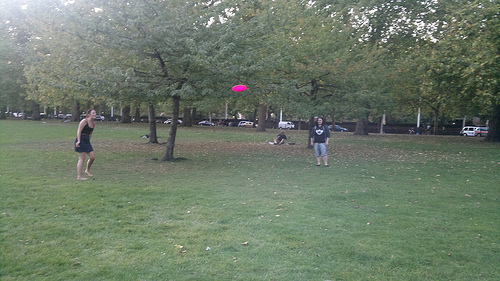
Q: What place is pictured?
A: It is a park.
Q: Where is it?
A: This is at the park.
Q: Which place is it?
A: It is a park.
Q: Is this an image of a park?
A: Yes, it is showing a park.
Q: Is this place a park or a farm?
A: It is a park.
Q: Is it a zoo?
A: No, it is a park.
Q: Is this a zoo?
A: No, it is a park.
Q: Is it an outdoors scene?
A: Yes, it is outdoors.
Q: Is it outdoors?
A: Yes, it is outdoors.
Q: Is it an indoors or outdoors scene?
A: It is outdoors.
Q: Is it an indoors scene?
A: No, it is outdoors.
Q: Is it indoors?
A: No, it is outdoors.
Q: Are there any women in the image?
A: Yes, there is a woman.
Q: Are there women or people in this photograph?
A: Yes, there is a woman.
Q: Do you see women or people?
A: Yes, there is a woman.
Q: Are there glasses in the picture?
A: No, there are no glasses.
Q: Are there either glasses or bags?
A: No, there are no glasses or bags.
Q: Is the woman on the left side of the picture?
A: Yes, the woman is on the left of the image.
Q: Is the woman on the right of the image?
A: No, the woman is on the left of the image.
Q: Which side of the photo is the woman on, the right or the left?
A: The woman is on the left of the image.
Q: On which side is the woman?
A: The woman is on the left of the image.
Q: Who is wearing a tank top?
A: The woman is wearing a tank top.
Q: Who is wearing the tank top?
A: The woman is wearing a tank top.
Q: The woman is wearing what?
A: The woman is wearing a tank top.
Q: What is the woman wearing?
A: The woman is wearing a tank top.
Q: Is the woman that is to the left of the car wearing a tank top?
A: Yes, the woman is wearing a tank top.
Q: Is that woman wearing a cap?
A: No, the woman is wearing a tank top.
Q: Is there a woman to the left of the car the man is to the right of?
A: Yes, there is a woman to the left of the car.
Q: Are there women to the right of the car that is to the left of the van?
A: No, the woman is to the left of the car.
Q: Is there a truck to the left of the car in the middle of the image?
A: No, there is a woman to the left of the car.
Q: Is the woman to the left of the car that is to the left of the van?
A: Yes, the woman is to the left of the car.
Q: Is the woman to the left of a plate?
A: No, the woman is to the left of the car.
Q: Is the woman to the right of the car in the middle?
A: No, the woman is to the left of the car.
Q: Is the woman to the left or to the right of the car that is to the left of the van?
A: The woman is to the left of the car.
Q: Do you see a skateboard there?
A: No, there are no skateboards.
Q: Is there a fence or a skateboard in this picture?
A: No, there are no skateboards or fences.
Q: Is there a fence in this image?
A: No, there are no fences.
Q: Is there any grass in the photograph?
A: Yes, there is grass.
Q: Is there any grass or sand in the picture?
A: Yes, there is grass.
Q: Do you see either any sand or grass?
A: Yes, there is grass.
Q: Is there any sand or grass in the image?
A: Yes, there is grass.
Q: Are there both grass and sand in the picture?
A: No, there is grass but no sand.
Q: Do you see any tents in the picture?
A: No, there are no tents.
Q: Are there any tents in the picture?
A: No, there are no tents.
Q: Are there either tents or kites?
A: No, there are no tents or kites.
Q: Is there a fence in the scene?
A: No, there are no fences.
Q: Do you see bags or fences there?
A: No, there are no fences or bags.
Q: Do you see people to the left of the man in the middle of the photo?
A: Yes, there is a person to the left of the man.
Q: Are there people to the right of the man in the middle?
A: No, the person is to the left of the man.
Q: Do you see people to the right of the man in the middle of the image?
A: No, the person is to the left of the man.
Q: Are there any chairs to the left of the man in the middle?
A: No, there is a person to the left of the man.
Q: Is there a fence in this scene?
A: No, there are no fences.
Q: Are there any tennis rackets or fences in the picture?
A: No, there are no fences or tennis rackets.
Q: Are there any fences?
A: No, there are no fences.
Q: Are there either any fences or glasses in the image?
A: No, there are no fences or glasses.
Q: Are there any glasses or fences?
A: No, there are no fences or glasses.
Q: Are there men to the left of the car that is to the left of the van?
A: Yes, there is a man to the left of the car.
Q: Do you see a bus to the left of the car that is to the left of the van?
A: No, there is a man to the left of the car.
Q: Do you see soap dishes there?
A: No, there are no soap dishes.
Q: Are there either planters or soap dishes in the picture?
A: No, there are no soap dishes or planters.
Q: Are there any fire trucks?
A: No, there are no fire trucks.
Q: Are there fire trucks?
A: No, there are no fire trucks.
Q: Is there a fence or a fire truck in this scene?
A: No, there are no fire trucks or fences.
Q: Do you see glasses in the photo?
A: No, there are no glasses.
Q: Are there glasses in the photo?
A: No, there are no glasses.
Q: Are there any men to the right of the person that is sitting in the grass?
A: Yes, there is a man to the right of the person.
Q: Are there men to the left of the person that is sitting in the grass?
A: No, the man is to the right of the person.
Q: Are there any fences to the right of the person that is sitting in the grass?
A: No, there is a man to the right of the person.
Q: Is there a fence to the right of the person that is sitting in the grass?
A: No, there is a man to the right of the person.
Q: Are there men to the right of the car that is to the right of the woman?
A: Yes, there is a man to the right of the car.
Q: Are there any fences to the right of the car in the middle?
A: No, there is a man to the right of the car.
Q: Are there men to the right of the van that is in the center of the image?
A: Yes, there is a man to the right of the van.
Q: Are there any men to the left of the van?
A: No, the man is to the right of the van.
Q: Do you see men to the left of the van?
A: No, the man is to the right of the van.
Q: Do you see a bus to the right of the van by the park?
A: No, there is a man to the right of the van.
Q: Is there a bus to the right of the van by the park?
A: No, there is a man to the right of the van.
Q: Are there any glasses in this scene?
A: No, there are no glasses.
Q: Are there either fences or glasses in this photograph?
A: No, there are no glasses or fences.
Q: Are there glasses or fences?
A: No, there are no fences or glasses.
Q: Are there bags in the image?
A: No, there are no bags.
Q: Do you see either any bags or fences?
A: No, there are no bags or fences.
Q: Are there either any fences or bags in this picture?
A: No, there are no bags or fences.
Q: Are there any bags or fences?
A: No, there are no bags or fences.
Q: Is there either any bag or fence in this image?
A: No, there are no bags or fences.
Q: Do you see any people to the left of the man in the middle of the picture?
A: Yes, there is a person to the left of the man.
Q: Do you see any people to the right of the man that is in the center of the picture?
A: No, the person is to the left of the man.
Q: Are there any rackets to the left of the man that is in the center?
A: No, there is a person to the left of the man.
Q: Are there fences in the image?
A: No, there are no fences.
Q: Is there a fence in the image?
A: No, there are no fences.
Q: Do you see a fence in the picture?
A: No, there are no fences.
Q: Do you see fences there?
A: No, there are no fences.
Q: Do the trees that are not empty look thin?
A: No, the trees are thick.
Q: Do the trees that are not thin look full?
A: Yes, the trees are full.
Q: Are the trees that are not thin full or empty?
A: The trees are full.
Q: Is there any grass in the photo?
A: Yes, there is grass.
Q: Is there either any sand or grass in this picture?
A: Yes, there is grass.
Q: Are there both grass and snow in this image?
A: No, there is grass but no snow.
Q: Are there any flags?
A: No, there are no flags.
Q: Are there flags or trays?
A: No, there are no flags or trays.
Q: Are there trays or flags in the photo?
A: No, there are no flags or trays.